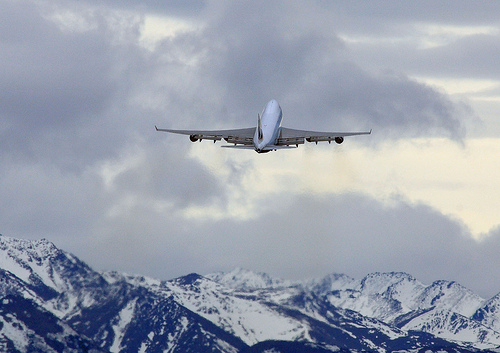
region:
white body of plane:
[249, 85, 289, 162]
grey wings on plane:
[140, 114, 377, 151]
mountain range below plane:
[9, 209, 497, 350]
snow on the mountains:
[8, 216, 498, 351]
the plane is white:
[145, 63, 388, 173]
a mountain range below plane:
[14, 208, 499, 351]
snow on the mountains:
[19, 206, 496, 342]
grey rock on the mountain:
[11, 214, 483, 351]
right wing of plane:
[289, 113, 376, 168]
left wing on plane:
[154, 110, 245, 148]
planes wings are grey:
[154, 114, 377, 159]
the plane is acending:
[151, 80, 376, 172]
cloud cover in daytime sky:
[0, 0, 497, 297]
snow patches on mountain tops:
[0, 234, 498, 351]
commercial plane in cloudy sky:
[0, 0, 498, 297]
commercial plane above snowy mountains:
[1, 97, 497, 351]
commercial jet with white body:
[153, 99, 371, 154]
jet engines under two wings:
[155, 127, 372, 153]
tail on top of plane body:
[253, 98, 282, 151]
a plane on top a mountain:
[0, 84, 497, 351]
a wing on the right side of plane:
[281, 119, 373, 150]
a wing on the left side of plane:
[147, 115, 256, 152]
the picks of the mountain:
[1, 230, 497, 351]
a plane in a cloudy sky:
[3, 4, 498, 239]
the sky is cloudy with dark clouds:
[1, 6, 492, 245]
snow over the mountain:
[1, 221, 499, 350]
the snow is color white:
[315, 264, 499, 351]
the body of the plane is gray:
[247, 89, 291, 161]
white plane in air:
[160, 93, 367, 161]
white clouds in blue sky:
[397, 163, 455, 208]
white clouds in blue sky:
[53, 38, 98, 66]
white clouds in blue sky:
[56, 96, 101, 134]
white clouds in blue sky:
[146, 192, 214, 229]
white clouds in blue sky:
[263, 189, 330, 230]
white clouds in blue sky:
[232, 21, 269, 42]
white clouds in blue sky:
[409, 52, 473, 113]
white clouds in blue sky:
[313, 13, 364, 64]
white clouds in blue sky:
[203, 223, 238, 250]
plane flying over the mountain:
[1, 91, 498, 348]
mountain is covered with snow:
[0, 219, 499, 346]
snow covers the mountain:
[3, 234, 494, 351]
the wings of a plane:
[153, 121, 380, 151]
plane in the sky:
[151, 105, 371, 166]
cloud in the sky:
[372, 63, 471, 147]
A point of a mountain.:
[186, 270, 201, 280]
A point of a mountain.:
[434, 279, 449, 285]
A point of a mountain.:
[431, 302, 443, 311]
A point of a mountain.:
[363, 268, 410, 278]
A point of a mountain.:
[329, 272, 353, 280]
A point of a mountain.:
[232, 267, 244, 270]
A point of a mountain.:
[35, 235, 48, 244]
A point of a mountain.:
[6, 293, 14, 299]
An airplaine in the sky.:
[156, 91, 366, 153]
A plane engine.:
[333, 135, 341, 145]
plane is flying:
[153, 98, 373, 157]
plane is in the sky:
[151, 97, 374, 155]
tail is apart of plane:
[258, 108, 263, 140]